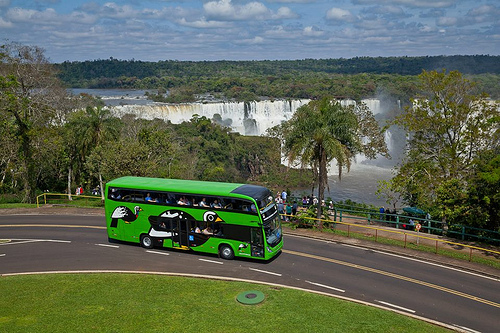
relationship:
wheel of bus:
[139, 233, 154, 248] [101, 169, 286, 264]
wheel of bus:
[218, 241, 233, 258] [101, 169, 286, 264]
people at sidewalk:
[273, 189, 420, 231] [333, 220, 483, 255]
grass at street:
[0, 270, 460, 331] [0, 212, 497, 330]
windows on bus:
[108, 182, 266, 212] [101, 169, 286, 264]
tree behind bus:
[271, 91, 368, 226] [101, 169, 286, 264]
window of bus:
[256, 211, 286, 244] [80, 160, 307, 272]